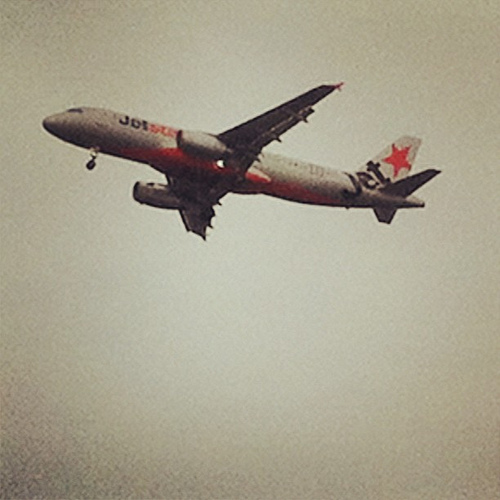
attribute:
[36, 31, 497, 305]
plane — brand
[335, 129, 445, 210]
emblem — red, star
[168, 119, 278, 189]
engine — large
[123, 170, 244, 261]
engine — large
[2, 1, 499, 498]
sky — gray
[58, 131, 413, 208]
plane's underside — plane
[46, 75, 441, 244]
plane — mostly white, white, orange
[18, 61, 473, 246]
plane — tan, red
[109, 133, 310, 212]
underneath — red